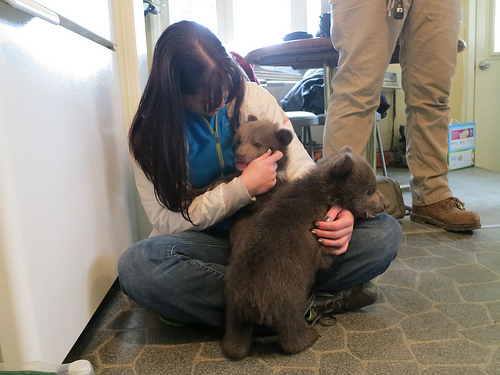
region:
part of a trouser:
[343, 27, 385, 74]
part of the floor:
[432, 307, 472, 359]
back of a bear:
[241, 277, 279, 345]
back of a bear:
[268, 192, 296, 249]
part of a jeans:
[146, 266, 194, 294]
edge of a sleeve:
[233, 175, 253, 206]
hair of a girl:
[143, 115, 170, 190]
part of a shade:
[127, 325, 177, 365]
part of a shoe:
[453, 210, 494, 238]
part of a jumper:
[250, 94, 282, 116]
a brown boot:
[410, 198, 482, 233]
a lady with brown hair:
[152, 20, 242, 124]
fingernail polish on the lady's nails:
[308, 215, 324, 254]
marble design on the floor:
[373, 305, 485, 370]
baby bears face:
[354, 154, 392, 220]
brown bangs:
[205, 60, 242, 115]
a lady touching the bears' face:
[230, 114, 287, 191]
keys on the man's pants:
[385, 0, 410, 23]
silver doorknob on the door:
[473, 1, 496, 171]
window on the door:
[475, 0, 497, 56]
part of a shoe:
[460, 221, 482, 236]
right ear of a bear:
[338, 156, 355, 181]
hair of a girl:
[143, 140, 182, 198]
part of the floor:
[408, 265, 461, 327]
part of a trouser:
[406, 118, 447, 178]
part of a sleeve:
[226, 182, 248, 213]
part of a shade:
[92, 147, 128, 222]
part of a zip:
[210, 134, 229, 159]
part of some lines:
[417, 287, 441, 319]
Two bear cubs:
[234, 110, 381, 355]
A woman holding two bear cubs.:
[144, 14, 298, 212]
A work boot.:
[401, 189, 495, 238]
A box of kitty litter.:
[437, 112, 477, 177]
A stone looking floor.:
[405, 235, 498, 371]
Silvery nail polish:
[315, 211, 344, 257]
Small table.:
[225, 17, 484, 75]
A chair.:
[232, 48, 323, 133]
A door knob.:
[473, 53, 496, 79]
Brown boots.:
[320, 280, 393, 320]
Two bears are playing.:
[221, 127, 383, 354]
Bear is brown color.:
[235, 225, 306, 311]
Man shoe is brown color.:
[403, 175, 488, 246]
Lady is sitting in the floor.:
[125, 83, 392, 371]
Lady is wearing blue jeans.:
[117, 252, 199, 297]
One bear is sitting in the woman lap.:
[195, 128, 275, 213]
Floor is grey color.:
[405, 282, 485, 367]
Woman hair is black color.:
[137, 98, 174, 178]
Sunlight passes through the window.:
[171, 5, 331, 55]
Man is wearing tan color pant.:
[337, 25, 448, 141]